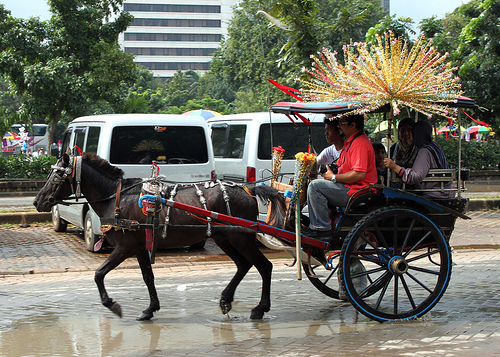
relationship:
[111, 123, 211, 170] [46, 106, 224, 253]
window on vehicle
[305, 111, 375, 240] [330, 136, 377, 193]
man wearing shirt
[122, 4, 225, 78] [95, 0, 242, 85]
window wearing building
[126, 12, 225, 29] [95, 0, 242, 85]
window wearing building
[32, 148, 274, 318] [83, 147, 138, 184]
horse has mane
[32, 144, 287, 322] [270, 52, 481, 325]
horse pulling buggy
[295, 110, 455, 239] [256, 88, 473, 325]
people riding buggy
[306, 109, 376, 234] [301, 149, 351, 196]
man holding camera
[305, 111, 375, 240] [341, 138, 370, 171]
man in shirt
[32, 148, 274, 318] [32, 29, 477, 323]
horse pulling carriage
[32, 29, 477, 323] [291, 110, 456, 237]
carriage of people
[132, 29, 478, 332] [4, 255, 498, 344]
carriage in water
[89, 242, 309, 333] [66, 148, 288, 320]
legs of horse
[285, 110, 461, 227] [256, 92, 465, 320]
people in carriage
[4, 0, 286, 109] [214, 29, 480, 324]
trees behind carriage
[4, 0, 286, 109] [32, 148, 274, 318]
trees behind horse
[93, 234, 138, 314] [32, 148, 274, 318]
leg of horse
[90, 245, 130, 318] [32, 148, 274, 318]
leg of horse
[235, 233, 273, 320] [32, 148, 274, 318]
leg of horse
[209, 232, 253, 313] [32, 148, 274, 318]
leg of horse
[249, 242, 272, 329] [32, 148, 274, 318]
leg of horse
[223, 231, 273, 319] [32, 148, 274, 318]
leg of horse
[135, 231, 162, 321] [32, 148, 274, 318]
leg of horse